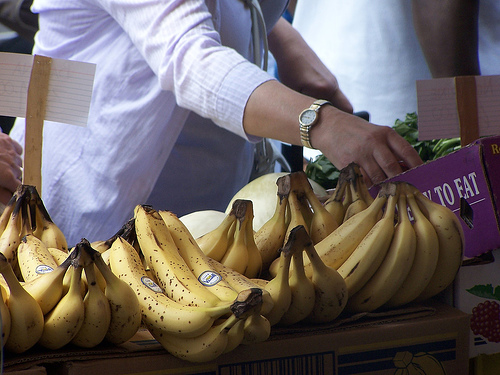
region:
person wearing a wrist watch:
[288, 95, 329, 137]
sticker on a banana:
[197, 260, 221, 295]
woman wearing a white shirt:
[62, 3, 235, 205]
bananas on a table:
[129, 208, 369, 334]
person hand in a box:
[340, 99, 477, 184]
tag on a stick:
[14, 46, 88, 128]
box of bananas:
[283, 315, 455, 373]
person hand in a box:
[114, 45, 421, 192]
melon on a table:
[218, 164, 335, 216]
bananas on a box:
[10, 182, 265, 354]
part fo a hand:
[353, 126, 378, 166]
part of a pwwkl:
[156, 298, 181, 315]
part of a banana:
[296, 250, 324, 292]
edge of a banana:
[178, 310, 220, 363]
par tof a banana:
[211, 336, 225, 353]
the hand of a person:
[328, 86, 452, 178]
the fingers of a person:
[324, 126, 401, 227]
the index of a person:
[378, 121, 420, 195]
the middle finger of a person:
[370, 126, 400, 193]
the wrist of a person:
[277, 63, 375, 154]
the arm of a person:
[95, 33, 335, 205]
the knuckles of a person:
[321, 76, 439, 184]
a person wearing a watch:
[280, 61, 357, 183]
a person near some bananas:
[74, 21, 388, 275]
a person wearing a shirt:
[92, 53, 333, 235]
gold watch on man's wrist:
[298, 95, 329, 154]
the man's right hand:
[327, 112, 428, 193]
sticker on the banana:
[197, 266, 225, 287]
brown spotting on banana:
[159, 269, 173, 281]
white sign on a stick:
[0, 48, 100, 130]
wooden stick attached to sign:
[17, 55, 54, 190]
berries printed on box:
[471, 293, 498, 349]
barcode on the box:
[221, 352, 338, 373]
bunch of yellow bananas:
[106, 202, 287, 369]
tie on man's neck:
[243, 1, 269, 84]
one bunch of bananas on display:
[103, 202, 274, 367]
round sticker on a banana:
[198, 268, 225, 285]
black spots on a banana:
[159, 253, 201, 304]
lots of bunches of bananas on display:
[1, 170, 470, 370]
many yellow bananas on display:
[2, 168, 472, 367]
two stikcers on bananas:
[139, 268, 227, 293]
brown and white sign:
[0, 48, 99, 198]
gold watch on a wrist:
[296, 97, 330, 144]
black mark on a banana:
[148, 226, 169, 248]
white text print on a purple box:
[446, 171, 482, 201]